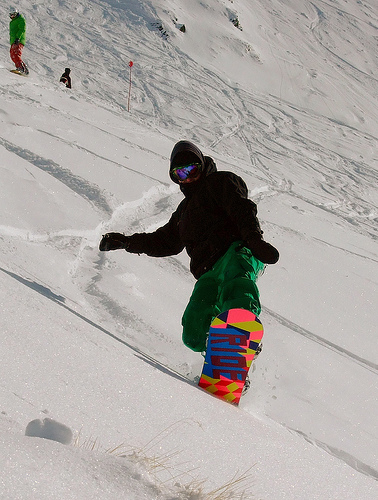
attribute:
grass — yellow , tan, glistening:
[81, 414, 266, 498]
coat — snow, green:
[9, 17, 24, 45]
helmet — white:
[6, 5, 17, 15]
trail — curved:
[58, 183, 185, 377]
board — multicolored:
[190, 303, 266, 411]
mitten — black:
[254, 240, 279, 264]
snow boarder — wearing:
[221, 35, 337, 137]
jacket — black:
[120, 166, 262, 278]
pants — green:
[177, 239, 268, 353]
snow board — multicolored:
[195, 306, 261, 422]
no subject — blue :
[279, 25, 376, 64]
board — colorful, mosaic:
[195, 307, 265, 406]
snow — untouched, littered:
[2, 1, 376, 497]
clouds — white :
[289, 150, 342, 211]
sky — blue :
[314, 473, 342, 491]